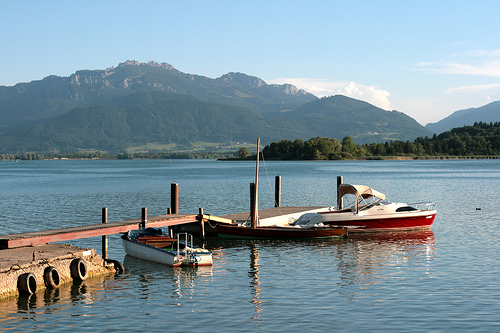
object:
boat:
[304, 177, 435, 234]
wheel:
[45, 267, 62, 288]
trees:
[256, 120, 499, 162]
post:
[249, 182, 258, 228]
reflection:
[247, 245, 260, 273]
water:
[3, 157, 496, 326]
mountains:
[2, 57, 489, 167]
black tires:
[16, 272, 41, 296]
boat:
[120, 228, 213, 268]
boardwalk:
[0, 207, 332, 250]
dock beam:
[273, 177, 283, 206]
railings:
[343, 193, 376, 210]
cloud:
[270, 70, 497, 123]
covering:
[338, 184, 383, 201]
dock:
[0, 213, 233, 265]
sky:
[0, 0, 499, 60]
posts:
[170, 181, 179, 216]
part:
[330, 17, 360, 46]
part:
[48, 281, 57, 288]